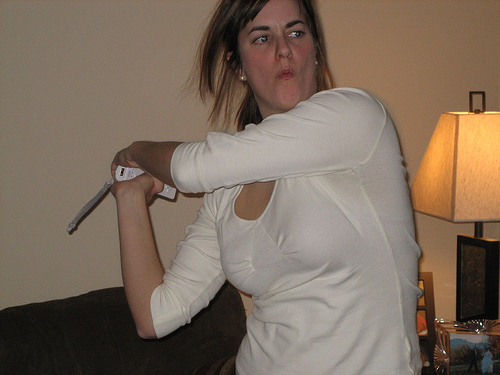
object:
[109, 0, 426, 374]
woman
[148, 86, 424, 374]
shirt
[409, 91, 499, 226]
lamp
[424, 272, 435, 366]
edge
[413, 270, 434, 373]
chair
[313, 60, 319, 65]
earring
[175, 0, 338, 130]
hair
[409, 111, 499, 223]
shade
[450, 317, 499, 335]
ashtray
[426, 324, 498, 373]
table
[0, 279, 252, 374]
sofa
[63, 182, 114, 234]
strap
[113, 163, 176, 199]
controller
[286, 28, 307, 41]
eye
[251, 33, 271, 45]
eye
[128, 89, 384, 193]
arm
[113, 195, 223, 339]
arm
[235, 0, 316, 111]
face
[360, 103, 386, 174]
line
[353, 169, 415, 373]
line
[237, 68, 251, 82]
earring